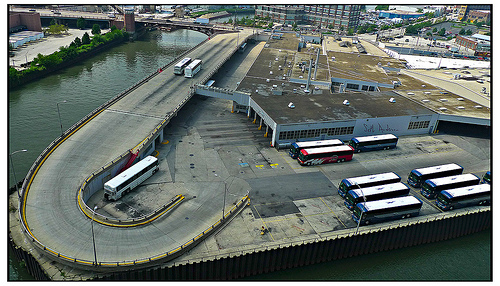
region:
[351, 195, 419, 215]
bus on the road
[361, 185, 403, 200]
bus on the road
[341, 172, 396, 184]
bus on the road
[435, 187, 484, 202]
bus on the road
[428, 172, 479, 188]
bus on the road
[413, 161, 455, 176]
bus on the road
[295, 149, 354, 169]
bus on the road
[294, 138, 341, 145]
bus on the road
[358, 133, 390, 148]
bus on the road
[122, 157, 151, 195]
bus on the road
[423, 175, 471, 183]
bus on the road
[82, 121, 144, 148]
Road in the photo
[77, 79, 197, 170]
Bridge in the photo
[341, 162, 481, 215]
Buses in the parking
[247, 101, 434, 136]
A building in the photo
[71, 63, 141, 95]
A river in the photo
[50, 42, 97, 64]
Trees in the photo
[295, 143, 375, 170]
Red and white bus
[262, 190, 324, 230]
A parking bay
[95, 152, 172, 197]
A white bus near the bridge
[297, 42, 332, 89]
Pillars in the photo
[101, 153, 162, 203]
white bus parked at bus station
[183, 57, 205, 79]
white bus driving on highway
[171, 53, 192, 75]
bus driving on highway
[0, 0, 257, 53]
bridge across river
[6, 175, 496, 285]
dark brown fence around bus station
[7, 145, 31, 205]
gray metal light pole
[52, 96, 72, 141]
gray metal light pole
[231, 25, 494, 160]
large white and gray bus station near river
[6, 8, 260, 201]
river running through city near bus station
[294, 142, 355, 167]
red bus parked in bus station parking lot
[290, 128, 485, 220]
The buses are parked next to each other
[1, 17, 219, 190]
Water underneath the bridge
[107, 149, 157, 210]
The bus is white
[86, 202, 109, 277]
The light pole is tall and grey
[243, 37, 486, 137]
The building has a black roof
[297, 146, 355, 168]
The bus is red and white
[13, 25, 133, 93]
Bushes and trees next to the water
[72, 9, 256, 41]
Cars and trucks on the bridge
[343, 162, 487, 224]
The buses are blue and white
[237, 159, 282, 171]
The grates on the ground are yellow and blue